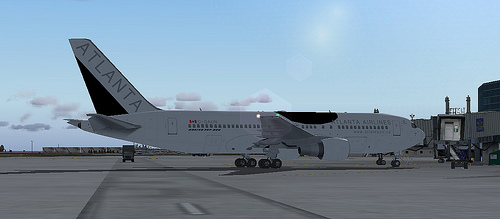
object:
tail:
[65, 37, 166, 149]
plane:
[64, 37, 429, 172]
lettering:
[75, 40, 142, 113]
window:
[186, 122, 192, 127]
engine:
[296, 134, 353, 163]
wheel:
[392, 158, 401, 167]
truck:
[121, 143, 134, 162]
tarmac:
[0, 154, 498, 217]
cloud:
[7, 122, 53, 134]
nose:
[411, 125, 429, 151]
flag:
[187, 117, 201, 124]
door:
[392, 119, 401, 139]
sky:
[0, 0, 499, 146]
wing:
[256, 113, 334, 159]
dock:
[433, 109, 497, 152]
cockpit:
[406, 121, 424, 132]